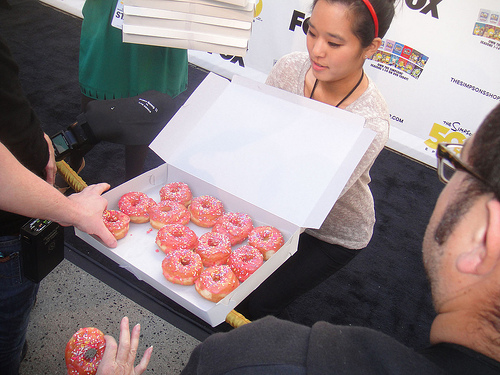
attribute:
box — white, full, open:
[62, 73, 377, 328]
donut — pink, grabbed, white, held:
[65, 323, 106, 374]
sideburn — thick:
[434, 181, 483, 244]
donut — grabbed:
[92, 202, 130, 246]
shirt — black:
[163, 310, 499, 371]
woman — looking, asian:
[199, 0, 396, 309]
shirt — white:
[254, 47, 390, 266]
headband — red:
[361, 0, 381, 40]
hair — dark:
[474, 98, 499, 188]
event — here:
[0, 0, 499, 375]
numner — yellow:
[418, 122, 446, 151]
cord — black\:
[285, 8, 310, 43]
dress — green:
[81, 0, 193, 99]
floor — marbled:
[281, 173, 441, 323]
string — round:
[306, 75, 372, 105]